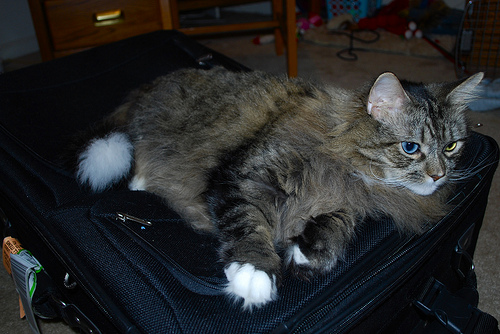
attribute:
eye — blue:
[399, 140, 419, 156]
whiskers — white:
[356, 149, 487, 204]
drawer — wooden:
[33, 3, 163, 42]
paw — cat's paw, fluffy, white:
[223, 262, 275, 312]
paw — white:
[220, 260, 282, 310]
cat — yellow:
[174, 48, 489, 263]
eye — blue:
[394, 134, 422, 163]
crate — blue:
[330, 0, 379, 21]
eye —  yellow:
[442, 136, 460, 153]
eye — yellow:
[442, 131, 464, 156]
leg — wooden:
[285, 0, 298, 78]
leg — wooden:
[272, 0, 287, 53]